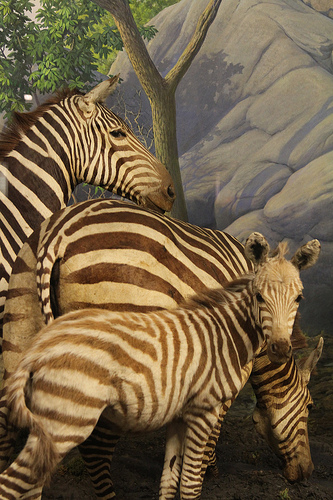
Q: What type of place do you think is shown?
A: It is a zoo.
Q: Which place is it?
A: It is a zoo.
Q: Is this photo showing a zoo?
A: Yes, it is showing a zoo.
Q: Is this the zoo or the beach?
A: It is the zoo.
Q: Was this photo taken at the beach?
A: No, the picture was taken in the zoo.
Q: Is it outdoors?
A: Yes, it is outdoors.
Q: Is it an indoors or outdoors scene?
A: It is outdoors.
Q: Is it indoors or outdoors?
A: It is outdoors.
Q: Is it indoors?
A: No, it is outdoors.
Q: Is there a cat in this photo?
A: No, there are no cats.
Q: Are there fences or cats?
A: No, there are no cats or fences.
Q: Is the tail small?
A: Yes, the tail is small.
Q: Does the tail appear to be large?
A: No, the tail is small.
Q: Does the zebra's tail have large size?
A: No, the tail is small.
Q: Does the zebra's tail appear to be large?
A: No, the tail is small.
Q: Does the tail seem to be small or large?
A: The tail is small.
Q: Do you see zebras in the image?
A: Yes, there is a zebra.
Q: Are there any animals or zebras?
A: Yes, there is a zebra.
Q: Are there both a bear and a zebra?
A: No, there is a zebra but no bears.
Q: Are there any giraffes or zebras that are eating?
A: Yes, the zebra is eating.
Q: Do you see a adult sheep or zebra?
A: Yes, there is an adult zebra.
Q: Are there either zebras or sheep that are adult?
A: Yes, the zebra is adult.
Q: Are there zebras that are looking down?
A: Yes, there is a zebra that is looking down.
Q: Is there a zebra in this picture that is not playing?
A: Yes, there is a zebra that is looking down.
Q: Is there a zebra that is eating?
A: Yes, there is a zebra that is eating.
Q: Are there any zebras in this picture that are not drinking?
A: Yes, there is a zebra that is eating.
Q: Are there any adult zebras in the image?
A: Yes, there is an adult zebra.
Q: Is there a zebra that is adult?
A: Yes, there is a zebra that is adult.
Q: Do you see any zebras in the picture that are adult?
A: Yes, there is a zebra that is adult.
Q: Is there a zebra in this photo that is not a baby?
A: Yes, there is a adult zebra.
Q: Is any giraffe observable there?
A: No, there are no giraffes.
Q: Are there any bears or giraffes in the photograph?
A: No, there are no giraffes or bears.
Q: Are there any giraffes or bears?
A: No, there are no giraffes or bears.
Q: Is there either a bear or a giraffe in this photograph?
A: No, there are no giraffes or bears.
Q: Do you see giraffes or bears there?
A: No, there are no giraffes or bears.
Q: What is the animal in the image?
A: The animal is a zebra.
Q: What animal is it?
A: The animal is a zebra.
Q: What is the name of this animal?
A: This is a zebra.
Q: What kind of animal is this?
A: This is a zebra.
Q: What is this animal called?
A: This is a zebra.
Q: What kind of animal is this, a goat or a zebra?
A: This is a zebra.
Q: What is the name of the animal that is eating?
A: The animal is a zebra.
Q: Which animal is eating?
A: The animal is a zebra.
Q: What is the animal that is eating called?
A: The animal is a zebra.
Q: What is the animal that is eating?
A: The animal is a zebra.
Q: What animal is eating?
A: The animal is a zebra.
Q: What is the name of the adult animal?
A: The animal is a zebra.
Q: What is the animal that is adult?
A: The animal is a zebra.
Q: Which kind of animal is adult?
A: The animal is a zebra.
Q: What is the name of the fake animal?
A: The animal is a zebra.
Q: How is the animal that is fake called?
A: The animal is a zebra.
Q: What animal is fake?
A: The animal is a zebra.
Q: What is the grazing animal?
A: The animal is a zebra.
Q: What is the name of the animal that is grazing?
A: The animal is a zebra.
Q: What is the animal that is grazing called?
A: The animal is a zebra.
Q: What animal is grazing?
A: The animal is a zebra.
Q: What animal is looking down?
A: The animal is a zebra.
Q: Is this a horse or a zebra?
A: This is a zebra.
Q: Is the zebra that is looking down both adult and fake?
A: Yes, the zebra is adult and fake.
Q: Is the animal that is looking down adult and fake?
A: Yes, the zebra is adult and fake.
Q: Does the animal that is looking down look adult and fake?
A: Yes, the zebra is adult and fake.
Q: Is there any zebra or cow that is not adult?
A: No, there is a zebra but it is adult.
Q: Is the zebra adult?
A: Yes, the zebra is adult.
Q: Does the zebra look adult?
A: Yes, the zebra is adult.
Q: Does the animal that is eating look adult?
A: Yes, the zebra is adult.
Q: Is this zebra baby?
A: No, the zebra is adult.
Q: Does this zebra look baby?
A: No, the zebra is adult.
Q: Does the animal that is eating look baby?
A: No, the zebra is adult.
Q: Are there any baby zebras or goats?
A: No, there is a zebra but it is adult.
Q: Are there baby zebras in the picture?
A: No, there is a zebra but it is adult.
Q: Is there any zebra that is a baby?
A: No, there is a zebra but it is adult.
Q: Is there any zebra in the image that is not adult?
A: No, there is a zebra but it is adult.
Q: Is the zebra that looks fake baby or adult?
A: The zebra is adult.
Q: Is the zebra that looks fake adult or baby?
A: The zebra is adult.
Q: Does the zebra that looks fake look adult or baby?
A: The zebra is adult.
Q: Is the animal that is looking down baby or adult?
A: The zebra is adult.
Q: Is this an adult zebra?
A: Yes, this is an adult zebra.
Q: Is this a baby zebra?
A: No, this is an adult zebra.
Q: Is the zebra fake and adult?
A: Yes, the zebra is fake and adult.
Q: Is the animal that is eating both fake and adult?
A: Yes, the zebra is fake and adult.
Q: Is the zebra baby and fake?
A: No, the zebra is fake but adult.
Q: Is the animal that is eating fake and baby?
A: No, the zebra is fake but adult.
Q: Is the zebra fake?
A: Yes, the zebra is fake.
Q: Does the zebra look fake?
A: Yes, the zebra is fake.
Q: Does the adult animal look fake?
A: Yes, the zebra is fake.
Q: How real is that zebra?
A: The zebra is fake.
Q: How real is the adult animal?
A: The zebra is fake.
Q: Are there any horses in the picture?
A: No, there are no horses.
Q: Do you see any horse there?
A: No, there are no horses.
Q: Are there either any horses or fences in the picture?
A: No, there are no horses or fences.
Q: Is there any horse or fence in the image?
A: No, there are no horses or fences.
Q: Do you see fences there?
A: No, there are no fences.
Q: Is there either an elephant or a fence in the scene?
A: No, there are no fences or elephants.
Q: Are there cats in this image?
A: No, there are no cats.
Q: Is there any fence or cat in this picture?
A: No, there are no cats or fences.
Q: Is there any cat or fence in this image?
A: No, there are no cats or fences.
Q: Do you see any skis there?
A: No, there are no skis.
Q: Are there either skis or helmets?
A: No, there are no skis or helmets.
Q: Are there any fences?
A: No, there are no fences.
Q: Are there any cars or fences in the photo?
A: No, there are no fences or cars.